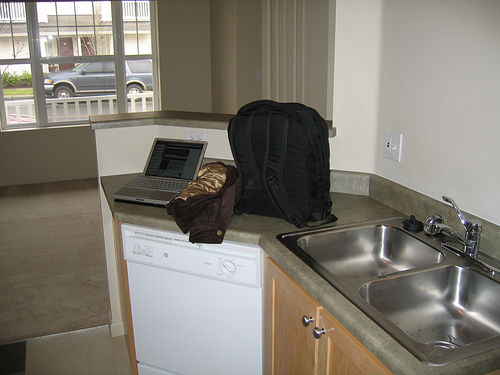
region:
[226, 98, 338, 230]
black back pack on counter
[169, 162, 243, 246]
brown and gold jacket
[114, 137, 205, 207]
open laptop on counter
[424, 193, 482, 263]
faucet on back of sink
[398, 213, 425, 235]
black sink drain plug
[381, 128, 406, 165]
outlet with light switch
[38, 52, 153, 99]
truck outside of window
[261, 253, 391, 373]
two brown cabinet doors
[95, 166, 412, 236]
marble counter top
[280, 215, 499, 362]
double sided stainless steel sink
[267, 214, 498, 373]
Silver double sink in kitchen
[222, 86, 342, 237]
Black backpack sitting on the counter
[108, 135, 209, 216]
Silver laptop sitting on the counter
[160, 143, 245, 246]
Brown and gold jacket sitting on counter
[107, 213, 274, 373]
White dishwasher in the kitchen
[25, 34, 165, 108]
Cark parked outside window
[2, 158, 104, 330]
Tan carpet in the living room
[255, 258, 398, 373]
Silver hardware on the cabinets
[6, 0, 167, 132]
White window frame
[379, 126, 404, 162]
Switch and outlet on the wall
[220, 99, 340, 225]
black backpack on the counter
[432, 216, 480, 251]
silver faucet of the sink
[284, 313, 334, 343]
silver knobs on the cupboards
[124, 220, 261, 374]
white dishwasher under counter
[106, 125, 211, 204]
laptop on the counter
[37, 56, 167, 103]
blue car parked on the road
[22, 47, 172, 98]
windows on the building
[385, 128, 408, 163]
white light switch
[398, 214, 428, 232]
black sink stopper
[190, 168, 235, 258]
dark brown jacket with tan lining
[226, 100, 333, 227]
A black back pack.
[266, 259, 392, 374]
Wooden cabinets under the sink.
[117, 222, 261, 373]
A white dishwasher.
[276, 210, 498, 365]
A silver kitchen sink.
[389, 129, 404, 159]
A white light switch.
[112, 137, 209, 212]
A silver laptop computer.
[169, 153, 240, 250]
A brown and gold coat.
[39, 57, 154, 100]
A blue SUV.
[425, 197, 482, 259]
A silver sink faucet.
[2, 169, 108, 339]
Beige colored carpet.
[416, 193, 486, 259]
a kitchen sink faucet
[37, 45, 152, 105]
a large blue suv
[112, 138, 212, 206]
a small gray laptop computer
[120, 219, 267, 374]
part of a white dishwasher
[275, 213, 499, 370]
a silver kitchen sink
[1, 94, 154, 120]
a white rail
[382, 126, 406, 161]
a white wall outlet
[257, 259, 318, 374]
part of a brown cabinet door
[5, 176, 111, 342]
brown carpet